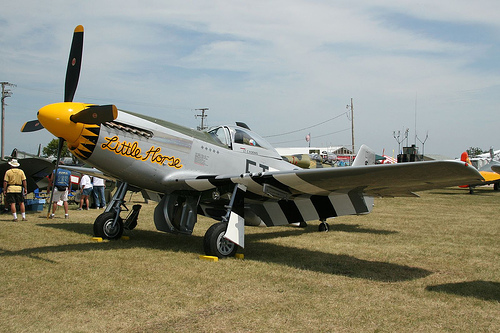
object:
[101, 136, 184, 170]
cursive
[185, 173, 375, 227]
stripe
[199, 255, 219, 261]
blocks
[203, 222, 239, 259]
tire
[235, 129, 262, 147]
windshield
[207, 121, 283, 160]
cockpit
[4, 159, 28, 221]
man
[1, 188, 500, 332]
grass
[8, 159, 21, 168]
hat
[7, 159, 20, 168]
man's head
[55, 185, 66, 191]
bag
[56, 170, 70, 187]
man's back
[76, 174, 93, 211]
women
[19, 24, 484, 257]
airplane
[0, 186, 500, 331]
ground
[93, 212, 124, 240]
wheel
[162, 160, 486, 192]
wing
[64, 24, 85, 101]
blade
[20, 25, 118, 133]
propeller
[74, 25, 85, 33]
tips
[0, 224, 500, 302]
shadow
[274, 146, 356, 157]
roof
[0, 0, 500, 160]
background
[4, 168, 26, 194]
shirt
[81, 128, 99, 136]
triangle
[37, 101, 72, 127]
nose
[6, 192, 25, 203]
shorts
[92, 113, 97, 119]
stripes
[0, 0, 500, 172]
sky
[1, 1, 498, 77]
clouds